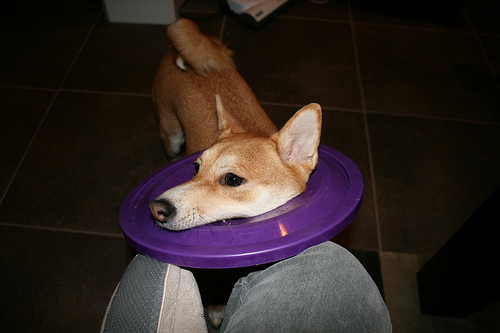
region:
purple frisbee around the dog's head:
[112, 127, 370, 264]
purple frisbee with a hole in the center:
[111, 134, 373, 262]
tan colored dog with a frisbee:
[107, 21, 319, 235]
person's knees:
[91, 235, 392, 327]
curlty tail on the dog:
[161, 18, 239, 73]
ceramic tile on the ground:
[1, 0, 493, 325]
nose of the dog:
[147, 195, 175, 225]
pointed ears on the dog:
[201, 90, 332, 181]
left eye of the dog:
[217, 173, 248, 191]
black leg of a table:
[415, 200, 492, 321]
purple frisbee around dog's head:
[114, 130, 372, 273]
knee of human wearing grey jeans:
[209, 233, 408, 330]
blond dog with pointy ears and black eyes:
[136, 16, 336, 229]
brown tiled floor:
[7, 0, 497, 312]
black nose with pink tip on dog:
[148, 198, 178, 219]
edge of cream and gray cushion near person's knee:
[109, 245, 208, 329]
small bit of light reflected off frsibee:
[276, 215, 288, 234]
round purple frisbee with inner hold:
[122, 123, 372, 264]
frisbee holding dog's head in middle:
[116, 103, 376, 270]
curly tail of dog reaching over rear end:
[164, 17, 228, 77]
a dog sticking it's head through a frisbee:
[117, 111, 389, 281]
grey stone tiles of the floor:
[6, 184, 91, 293]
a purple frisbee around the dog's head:
[128, 121, 343, 256]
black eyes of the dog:
[184, 156, 254, 195]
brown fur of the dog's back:
[192, 78, 242, 108]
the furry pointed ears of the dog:
[210, 91, 326, 156]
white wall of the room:
[110, 0, 176, 27]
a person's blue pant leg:
[238, 269, 383, 329]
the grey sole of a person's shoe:
[117, 281, 155, 319]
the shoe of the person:
[108, 257, 152, 310]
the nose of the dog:
[145, 200, 177, 227]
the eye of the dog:
[223, 168, 245, 190]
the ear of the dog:
[282, 96, 334, 171]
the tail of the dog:
[159, 30, 228, 75]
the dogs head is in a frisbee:
[138, 144, 327, 259]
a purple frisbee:
[131, 174, 297, 280]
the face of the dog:
[138, 98, 365, 275]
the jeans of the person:
[231, 265, 340, 325]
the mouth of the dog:
[168, 211, 256, 238]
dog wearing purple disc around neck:
[117, 138, 365, 268]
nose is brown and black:
[147, 195, 177, 222]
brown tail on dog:
[170, 10, 222, 71]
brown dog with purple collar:
[151, 18, 318, 233]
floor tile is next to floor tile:
[6, 86, 187, 236]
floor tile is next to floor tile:
[244, 102, 389, 310]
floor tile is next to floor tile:
[218, 13, 366, 108]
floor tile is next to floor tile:
[60, 8, 224, 90]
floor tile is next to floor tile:
[364, 103, 496, 245]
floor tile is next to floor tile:
[1, 89, 59, 200]